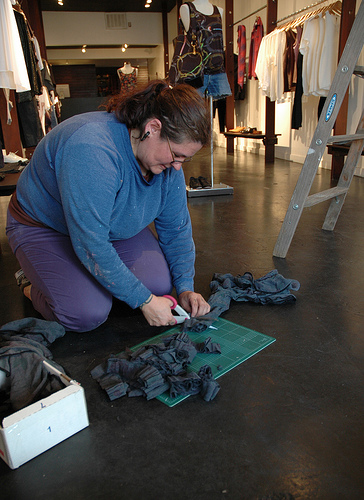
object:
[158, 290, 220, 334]
scissors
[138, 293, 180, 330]
hand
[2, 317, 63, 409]
clothing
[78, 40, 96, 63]
light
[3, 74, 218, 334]
lady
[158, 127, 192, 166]
glasses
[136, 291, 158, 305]
tattoo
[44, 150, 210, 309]
sleeve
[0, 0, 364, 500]
clothing store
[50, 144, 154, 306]
arm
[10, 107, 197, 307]
shirt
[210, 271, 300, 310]
fabric pieces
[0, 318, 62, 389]
fabric pieces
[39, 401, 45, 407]
seven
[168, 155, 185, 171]
nose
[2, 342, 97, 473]
box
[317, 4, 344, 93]
shirt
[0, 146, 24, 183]
shoes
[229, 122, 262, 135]
shoes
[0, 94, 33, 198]
stand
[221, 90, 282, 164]
stand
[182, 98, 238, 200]
stand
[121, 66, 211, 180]
head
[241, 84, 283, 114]
ground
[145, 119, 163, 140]
ear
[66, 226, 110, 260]
elbow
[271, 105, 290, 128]
wall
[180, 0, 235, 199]
mannequin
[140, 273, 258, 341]
cloth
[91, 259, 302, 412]
material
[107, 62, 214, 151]
hair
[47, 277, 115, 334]
knees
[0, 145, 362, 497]
floor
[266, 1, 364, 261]
rack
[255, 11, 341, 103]
clothes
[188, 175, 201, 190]
shoe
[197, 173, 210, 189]
shoe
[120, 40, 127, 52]
light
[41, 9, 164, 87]
wall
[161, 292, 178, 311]
handle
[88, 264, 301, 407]
fabric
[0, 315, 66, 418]
material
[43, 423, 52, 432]
number